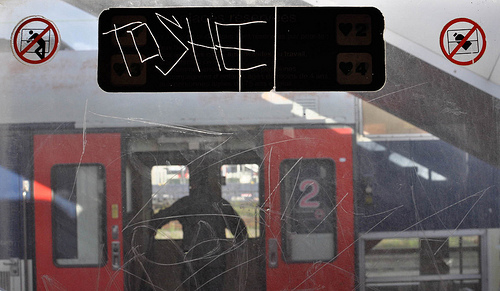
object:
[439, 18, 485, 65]
label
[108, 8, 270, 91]
graffiti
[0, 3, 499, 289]
window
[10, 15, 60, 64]
label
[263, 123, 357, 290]
door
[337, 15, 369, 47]
label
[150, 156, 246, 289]
person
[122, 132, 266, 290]
door way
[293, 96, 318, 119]
ac vent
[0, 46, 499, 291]
tram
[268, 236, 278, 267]
handle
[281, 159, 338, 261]
window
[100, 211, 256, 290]
scratches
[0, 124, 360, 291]
train car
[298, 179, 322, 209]
number 2